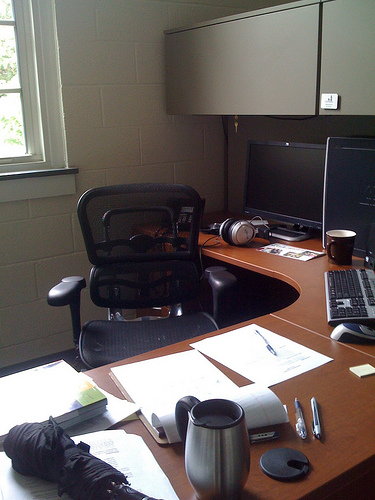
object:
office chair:
[47, 182, 235, 370]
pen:
[254, 330, 276, 355]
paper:
[189, 322, 335, 388]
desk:
[0, 212, 374, 500]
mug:
[175, 396, 250, 499]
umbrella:
[0, 421, 156, 500]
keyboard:
[324, 270, 374, 327]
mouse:
[330, 322, 374, 343]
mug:
[326, 230, 356, 264]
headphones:
[219, 218, 255, 246]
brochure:
[255, 242, 326, 262]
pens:
[294, 397, 308, 439]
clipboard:
[109, 369, 240, 443]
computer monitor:
[242, 140, 326, 228]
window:
[0, 0, 47, 166]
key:
[235, 122, 239, 132]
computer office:
[0, 0, 374, 497]